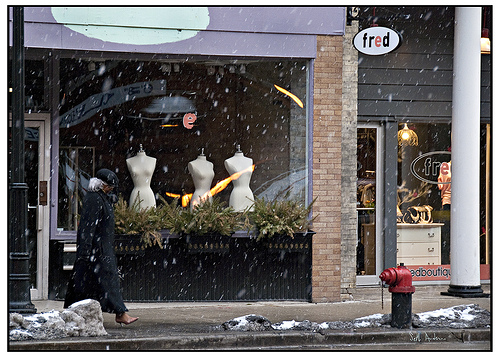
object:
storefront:
[8, 47, 342, 304]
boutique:
[8, 4, 358, 305]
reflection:
[61, 62, 199, 132]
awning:
[7, 5, 349, 59]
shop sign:
[351, 25, 403, 56]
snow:
[235, 316, 244, 321]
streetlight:
[394, 118, 419, 150]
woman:
[62, 167, 138, 327]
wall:
[311, 33, 344, 302]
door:
[356, 123, 383, 285]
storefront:
[393, 125, 454, 284]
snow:
[466, 315, 472, 319]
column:
[450, 5, 481, 291]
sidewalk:
[3, 282, 489, 344]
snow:
[423, 311, 443, 317]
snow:
[243, 253, 250, 260]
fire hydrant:
[378, 263, 415, 329]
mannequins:
[125, 152, 158, 212]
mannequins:
[187, 156, 216, 214]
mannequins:
[224, 152, 256, 213]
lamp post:
[8, 4, 34, 314]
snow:
[45, 311, 65, 325]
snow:
[91, 62, 107, 76]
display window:
[51, 56, 308, 241]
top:
[379, 262, 415, 295]